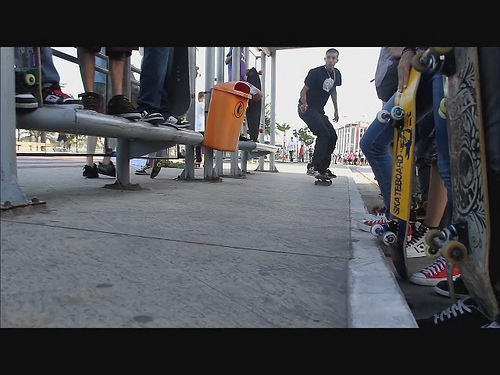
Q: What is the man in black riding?
A: Skateboard.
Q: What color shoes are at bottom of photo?
A: Black.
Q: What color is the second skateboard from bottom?
A: Yellow.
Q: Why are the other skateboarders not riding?
A: Waiting their turn.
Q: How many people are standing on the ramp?
A: 3.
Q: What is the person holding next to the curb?
A: A skateboard.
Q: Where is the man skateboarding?
A: A city sidewalk.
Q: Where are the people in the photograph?
A: Downtown.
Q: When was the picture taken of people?
A: Afternoon.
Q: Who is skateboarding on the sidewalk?
A: A man.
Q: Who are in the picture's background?
A: Teenagers.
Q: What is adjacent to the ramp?
A: A trash can.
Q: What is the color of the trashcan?
A: Orange.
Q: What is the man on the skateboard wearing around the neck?
A: A necklace.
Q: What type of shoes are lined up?
A: Skate shoes.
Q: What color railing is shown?
A: Grey.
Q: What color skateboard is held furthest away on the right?
A: Orange and black.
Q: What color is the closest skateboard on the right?
A: Black and white.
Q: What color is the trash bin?
A: Orange.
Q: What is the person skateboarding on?
A: Sidewalk.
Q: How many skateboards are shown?
A: Seven.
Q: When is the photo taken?
A: During the daytime.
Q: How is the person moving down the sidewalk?
A: On a skateboard.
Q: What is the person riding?
A: A skateboard.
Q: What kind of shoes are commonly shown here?
A: Sneakers.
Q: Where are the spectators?
A: Along the curb.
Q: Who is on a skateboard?
A: A man.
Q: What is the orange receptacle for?
A: Trash or recycling.